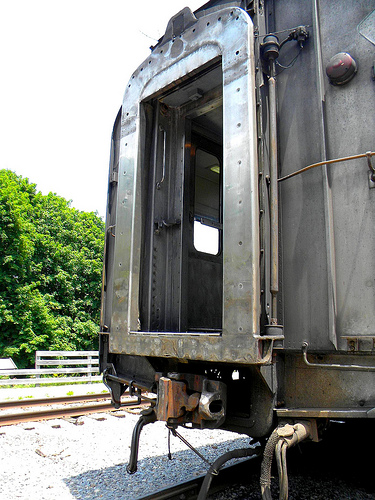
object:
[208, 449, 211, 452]
pebbles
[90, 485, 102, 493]
rocks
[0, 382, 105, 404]
pebbles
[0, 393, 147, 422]
tracks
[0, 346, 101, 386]
fence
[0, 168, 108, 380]
trees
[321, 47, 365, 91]
red light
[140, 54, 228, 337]
door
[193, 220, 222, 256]
window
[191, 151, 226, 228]
shade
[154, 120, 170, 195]
grab bar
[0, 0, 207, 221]
sky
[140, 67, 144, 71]
holes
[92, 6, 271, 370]
doorway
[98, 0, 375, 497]
train